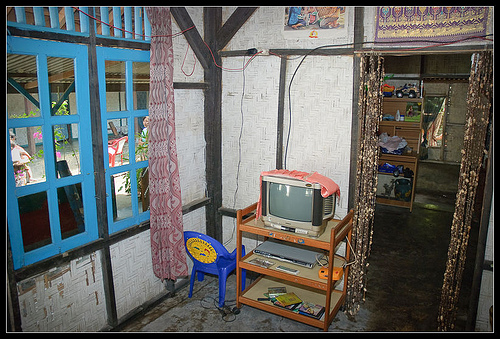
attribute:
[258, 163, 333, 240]
tv — close, silver, black, off, small, gray, white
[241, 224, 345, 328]
stand — brown, wooden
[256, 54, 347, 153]
wall — gray, white, dirty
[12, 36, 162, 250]
window — blue, open, close, light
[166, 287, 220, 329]
floor — dirty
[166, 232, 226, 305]
chair — blue, small, still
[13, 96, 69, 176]
plant — green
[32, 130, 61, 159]
flowers — pink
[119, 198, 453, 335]
floor — dirty